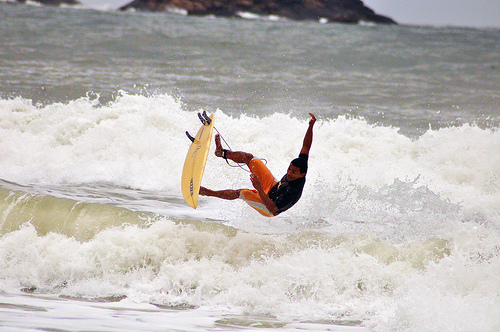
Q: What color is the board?
A: Yellow.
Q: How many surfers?
A: 1.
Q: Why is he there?
A: To surf.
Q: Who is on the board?
A: Surfer.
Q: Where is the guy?
A: Falling of the wave.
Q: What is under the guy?
A: Wave.